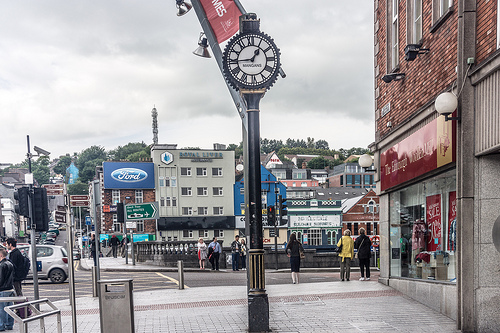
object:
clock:
[223, 34, 288, 93]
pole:
[216, 18, 300, 332]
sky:
[0, 5, 381, 152]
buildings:
[77, 131, 378, 259]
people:
[193, 228, 383, 282]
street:
[25, 260, 399, 307]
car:
[9, 239, 72, 285]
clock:
[217, 29, 286, 87]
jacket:
[330, 233, 358, 261]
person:
[327, 228, 361, 283]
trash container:
[93, 277, 135, 331]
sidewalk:
[38, 274, 458, 331]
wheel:
[45, 264, 70, 286]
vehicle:
[3, 241, 71, 286]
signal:
[7, 182, 56, 237]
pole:
[25, 229, 42, 316]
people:
[283, 225, 375, 285]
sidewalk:
[14, 282, 465, 331]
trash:
[90, 275, 140, 331]